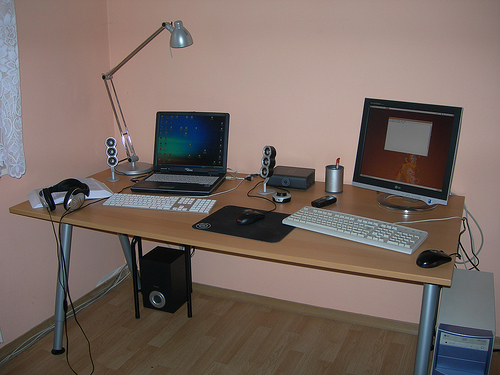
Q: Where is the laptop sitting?
A: On a desk.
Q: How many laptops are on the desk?
A: Two.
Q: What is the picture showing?
A: A workstation.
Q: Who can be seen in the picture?
A: No one.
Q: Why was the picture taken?
A: To capture the workstation.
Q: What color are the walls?
A: Pink.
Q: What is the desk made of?
A: Wood.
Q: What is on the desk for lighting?
A: A lamp.